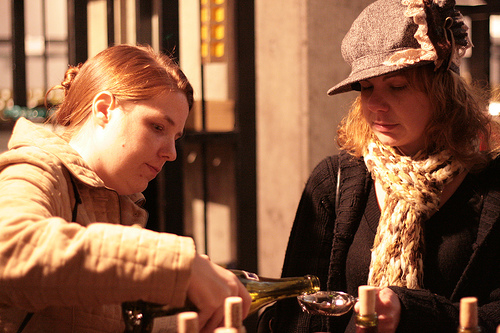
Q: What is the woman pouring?
A: Wine.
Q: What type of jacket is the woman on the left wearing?
A: Brown and quilted.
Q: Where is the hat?
A: On the woman's head.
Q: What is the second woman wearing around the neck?
A: Scarf.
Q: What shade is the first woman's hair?
A: Red.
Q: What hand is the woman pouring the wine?
A: Right.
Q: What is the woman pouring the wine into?
A: Glass.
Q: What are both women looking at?
A: The wine bottle.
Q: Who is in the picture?
A: Two women.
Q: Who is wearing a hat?
A: The woman on the right.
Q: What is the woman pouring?
A: Wine.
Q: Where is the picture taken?
A: An outdoor restaurant.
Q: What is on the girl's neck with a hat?
A: A scarf.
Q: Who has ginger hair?
A: The girl on the left.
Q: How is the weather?
A: Sunny.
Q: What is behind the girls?
A: A building.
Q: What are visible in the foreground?
A: Corks.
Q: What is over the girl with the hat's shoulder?
A: A purse strap.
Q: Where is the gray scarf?
A: On the woman in black.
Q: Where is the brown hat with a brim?
A: On the woman in black.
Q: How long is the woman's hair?
A: Short.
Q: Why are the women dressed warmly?
A: It is cold.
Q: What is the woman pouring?
A: Wine.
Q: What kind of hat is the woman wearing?
A: A flat brimmed hat.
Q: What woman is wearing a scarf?
A: The woman in black.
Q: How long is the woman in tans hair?
A: Long.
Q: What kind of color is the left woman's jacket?
A: Brown.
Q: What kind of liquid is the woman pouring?
A: Wine.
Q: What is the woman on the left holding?
A: A bottle.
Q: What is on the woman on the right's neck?
A: A scarf.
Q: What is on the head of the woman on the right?
A: A hat.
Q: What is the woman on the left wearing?
A: A coat.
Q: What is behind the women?
A: A building.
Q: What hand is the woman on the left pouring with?
A: The right hand.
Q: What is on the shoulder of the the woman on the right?
A: A strap.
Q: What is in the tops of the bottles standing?
A: Corks.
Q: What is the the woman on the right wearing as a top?
A: A brown swearter.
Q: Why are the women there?
A: To drink alcohol.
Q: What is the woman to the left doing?
A: Pouring liquor.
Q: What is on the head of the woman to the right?
A: A hat.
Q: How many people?
A: 2.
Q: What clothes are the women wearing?
A: Winter clothes.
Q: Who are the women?
A: Friends.